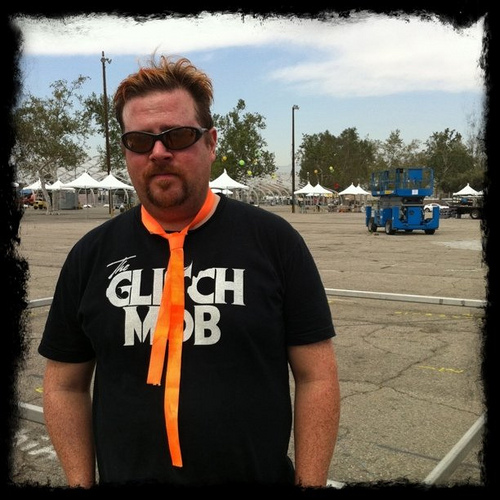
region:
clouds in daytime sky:
[19, 15, 484, 175]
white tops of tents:
[21, 167, 481, 211]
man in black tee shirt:
[40, 63, 340, 487]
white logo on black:
[107, 253, 246, 345]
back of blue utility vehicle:
[367, 166, 439, 231]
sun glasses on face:
[92, 115, 217, 160]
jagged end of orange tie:
[140, 363, 173, 390]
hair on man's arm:
[306, 410, 344, 448]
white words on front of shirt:
[107, 258, 246, 348]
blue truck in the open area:
[331, 151, 457, 254]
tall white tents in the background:
[275, 168, 364, 215]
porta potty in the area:
[44, 183, 94, 211]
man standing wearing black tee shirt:
[42, 191, 341, 484]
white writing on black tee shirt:
[99, 253, 241, 362]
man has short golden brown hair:
[112, 54, 219, 219]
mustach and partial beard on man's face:
[143, 162, 193, 213]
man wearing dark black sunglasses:
[123, 118, 209, 156]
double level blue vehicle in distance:
[362, 163, 444, 235]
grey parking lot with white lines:
[23, 217, 495, 480]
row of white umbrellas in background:
[16, 168, 484, 211]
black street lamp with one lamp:
[291, 95, 306, 219]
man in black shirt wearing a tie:
[39, 62, 341, 485]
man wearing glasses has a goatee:
[41, 56, 339, 483]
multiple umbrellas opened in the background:
[15, 172, 482, 214]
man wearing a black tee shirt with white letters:
[40, 58, 340, 487]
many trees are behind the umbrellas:
[18, 78, 480, 208]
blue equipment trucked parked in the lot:
[364, 168, 440, 233]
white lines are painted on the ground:
[20, 286, 483, 479]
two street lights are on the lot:
[101, 48, 300, 215]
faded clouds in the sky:
[21, 18, 481, 174]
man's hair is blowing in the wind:
[38, 45, 338, 484]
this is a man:
[49, 49, 455, 483]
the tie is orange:
[150, 245, 222, 393]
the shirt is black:
[135, 198, 328, 494]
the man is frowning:
[94, 55, 259, 211]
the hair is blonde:
[102, 56, 226, 165]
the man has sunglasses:
[124, 129, 214, 194]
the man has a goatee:
[131, 163, 228, 256]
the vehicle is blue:
[324, 124, 414, 248]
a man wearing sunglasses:
[121, 36, 401, 371]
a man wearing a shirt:
[75, 171, 395, 498]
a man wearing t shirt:
[38, 189, 315, 431]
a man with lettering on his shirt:
[95, 224, 262, 404]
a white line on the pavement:
[309, 255, 498, 350]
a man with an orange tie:
[106, 191, 256, 420]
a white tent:
[289, 165, 336, 220]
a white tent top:
[208, 168, 234, 188]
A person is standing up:
[64, 75, 325, 473]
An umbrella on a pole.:
[301, 182, 315, 192]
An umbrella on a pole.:
[340, 181, 355, 199]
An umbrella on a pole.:
[453, 187, 474, 197]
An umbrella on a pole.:
[96, 174, 126, 192]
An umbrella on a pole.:
[51, 181, 77, 196]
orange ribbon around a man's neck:
[139, 188, 214, 465]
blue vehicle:
[363, 165, 439, 232]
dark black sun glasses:
[121, 124, 213, 151]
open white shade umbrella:
[307, 181, 332, 198]